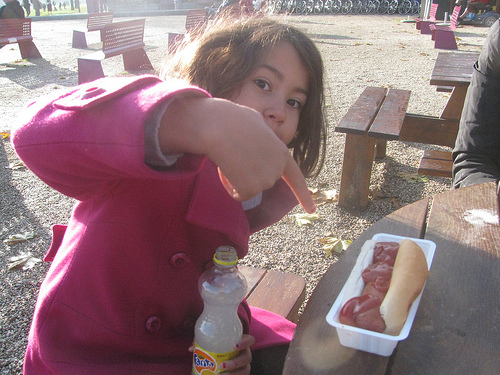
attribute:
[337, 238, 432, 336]
bun — warm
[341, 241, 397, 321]
ketchup — excessive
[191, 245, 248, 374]
bottle — plastic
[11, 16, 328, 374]
girl — sitting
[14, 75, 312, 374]
coat — pink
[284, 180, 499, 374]
table — wooden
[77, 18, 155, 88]
bench — red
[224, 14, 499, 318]
ground — gravel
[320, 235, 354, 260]
leaves — green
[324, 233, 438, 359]
container — plastic, white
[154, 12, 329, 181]
hair — brown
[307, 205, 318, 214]
fingernail — pink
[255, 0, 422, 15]
row — bicycles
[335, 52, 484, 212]
bench — wooden, dark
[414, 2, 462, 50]
pair — benches, pink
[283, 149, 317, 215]
finger — pointing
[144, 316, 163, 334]
button — plastic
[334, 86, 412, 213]
seat — brown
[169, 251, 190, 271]
button — pink, plastic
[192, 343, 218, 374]
label — orange, blue, fanta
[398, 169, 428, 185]
leaf — yellow